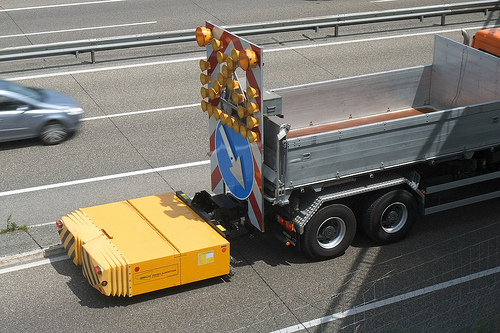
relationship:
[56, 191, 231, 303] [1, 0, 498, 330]
electronic sign on ground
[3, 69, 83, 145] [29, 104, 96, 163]
car has tire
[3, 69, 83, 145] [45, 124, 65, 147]
car has rim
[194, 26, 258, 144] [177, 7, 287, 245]
light on sign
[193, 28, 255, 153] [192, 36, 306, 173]
light on sign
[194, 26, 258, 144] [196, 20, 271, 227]
light on sign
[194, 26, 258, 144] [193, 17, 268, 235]
light on sign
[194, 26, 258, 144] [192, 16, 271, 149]
light on sign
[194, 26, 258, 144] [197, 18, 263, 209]
light on sign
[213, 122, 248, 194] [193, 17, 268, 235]
arrow on sign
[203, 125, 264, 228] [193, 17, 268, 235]
stripes are on sign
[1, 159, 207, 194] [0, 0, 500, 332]
line on road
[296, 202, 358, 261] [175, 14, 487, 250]
back tire are on back of truck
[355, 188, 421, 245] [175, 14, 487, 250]
back tire are on back of truck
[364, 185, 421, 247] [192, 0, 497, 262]
back tire on truck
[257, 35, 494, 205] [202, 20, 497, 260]
bed on truck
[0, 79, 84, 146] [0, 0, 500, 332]
car on road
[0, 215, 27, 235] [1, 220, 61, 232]
grass on line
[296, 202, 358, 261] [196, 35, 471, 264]
back tire of truck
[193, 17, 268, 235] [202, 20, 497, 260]
sign on back of truck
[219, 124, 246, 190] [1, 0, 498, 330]
arrow pointing to ground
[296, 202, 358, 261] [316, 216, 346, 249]
back tire on rim